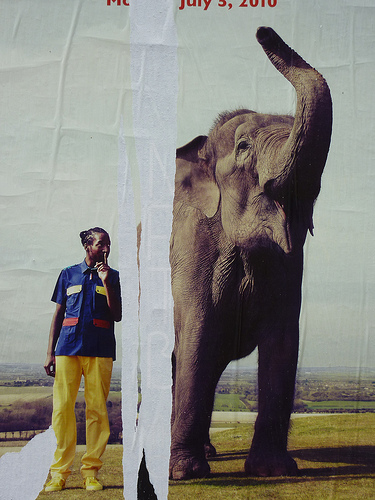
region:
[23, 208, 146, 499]
guy wearing blue shirt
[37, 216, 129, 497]
guy wearing blue shirt with four pockets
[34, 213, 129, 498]
guy wearing yellow pants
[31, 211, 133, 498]
guy with finger near mouth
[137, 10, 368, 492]
grey elephant on grass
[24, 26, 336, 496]
guy with elephant near him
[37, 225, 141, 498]
guy standing on grass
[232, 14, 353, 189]
elephant grey truck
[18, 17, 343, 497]
elephant standing near guy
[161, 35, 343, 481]
The elephant is standing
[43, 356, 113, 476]
Man wearing yellow pants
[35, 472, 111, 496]
Man wearing yellow shoes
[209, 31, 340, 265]
The elephant is opening its mouth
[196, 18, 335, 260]
The elephant is raising its trunk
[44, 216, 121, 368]
Man wearing a blue shirt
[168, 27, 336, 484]
The elephant is on grass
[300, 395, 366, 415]
Grass field behind the elephant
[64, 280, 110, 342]
Yellow and red pockets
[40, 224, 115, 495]
The man is standing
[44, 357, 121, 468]
the pants are yellow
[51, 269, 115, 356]
the shirt is blue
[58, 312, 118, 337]
the pocket flaps are red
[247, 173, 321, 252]
the mouth is open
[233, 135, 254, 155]
the eye is dark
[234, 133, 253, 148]
the elephant has an eye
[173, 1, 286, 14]
the date is written in red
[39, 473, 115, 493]
the shoes are yellow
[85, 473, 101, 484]
the shoe lace is yellow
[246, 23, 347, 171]
the elephant has a trunk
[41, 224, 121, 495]
man wearing yellow sneakers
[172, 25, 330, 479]
large grey elephant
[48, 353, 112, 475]
pair of wrinkles yellow pants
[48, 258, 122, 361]
blue short sleeve shirt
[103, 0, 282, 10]
red writing on white paper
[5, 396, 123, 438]
trees bare of leaves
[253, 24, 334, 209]
elephants trunk raised in the air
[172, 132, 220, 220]
large grey ear on side of head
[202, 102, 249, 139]
tufts of fur on elephant's head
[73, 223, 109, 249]
hair braided in cornrows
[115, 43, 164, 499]
the picture was damaged in the middle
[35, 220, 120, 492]
the man is beside the elephant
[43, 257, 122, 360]
the man has a blue shirt on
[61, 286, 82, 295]
the top of the pocket is yellow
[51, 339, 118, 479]
the mans pants are yellow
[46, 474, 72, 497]
the mans shoes are yellow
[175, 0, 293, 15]
the writing was cut off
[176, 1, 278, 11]
the writing is in red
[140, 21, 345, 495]
the elephants mouth is open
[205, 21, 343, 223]
the elephants trunk is in the air